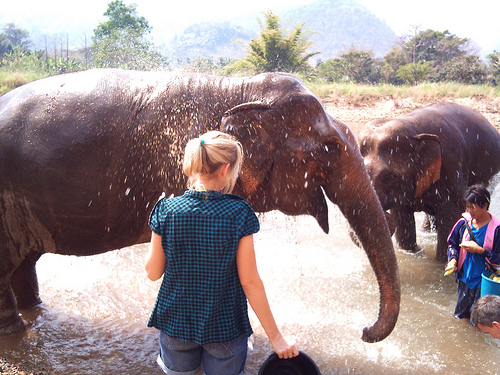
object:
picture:
[4, 2, 496, 374]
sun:
[5, 2, 498, 50]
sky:
[6, 0, 499, 35]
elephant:
[355, 94, 491, 269]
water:
[0, 243, 499, 375]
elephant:
[5, 60, 404, 351]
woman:
[139, 125, 297, 375]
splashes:
[1, 299, 94, 374]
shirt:
[145, 187, 259, 345]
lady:
[443, 181, 500, 323]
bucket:
[477, 266, 499, 295]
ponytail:
[178, 137, 208, 179]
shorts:
[151, 332, 253, 374]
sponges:
[486, 267, 499, 281]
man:
[468, 290, 499, 345]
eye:
[379, 171, 395, 185]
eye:
[320, 138, 345, 157]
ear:
[412, 131, 444, 200]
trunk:
[329, 162, 408, 345]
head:
[179, 130, 247, 197]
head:
[455, 183, 495, 218]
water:
[139, 92, 312, 148]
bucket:
[253, 350, 324, 374]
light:
[276, 232, 352, 310]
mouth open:
[315, 183, 345, 235]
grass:
[323, 79, 491, 96]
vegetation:
[1, 1, 500, 80]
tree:
[235, 6, 325, 77]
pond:
[255, 215, 439, 362]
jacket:
[440, 210, 499, 279]